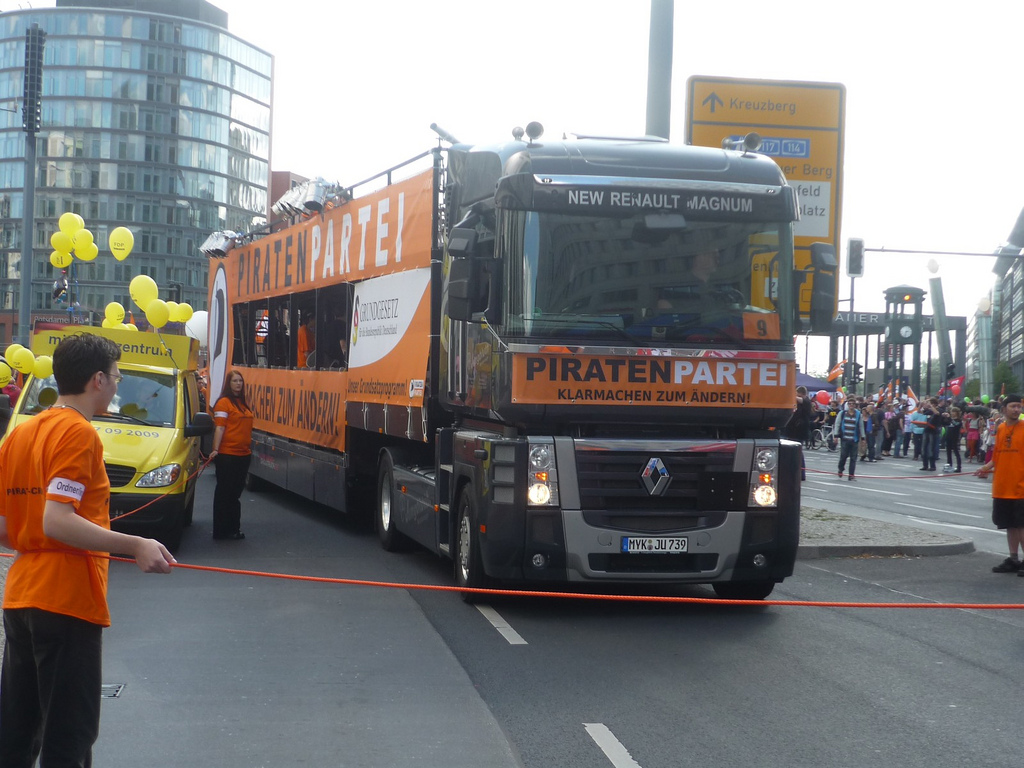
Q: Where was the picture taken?
A: City street.